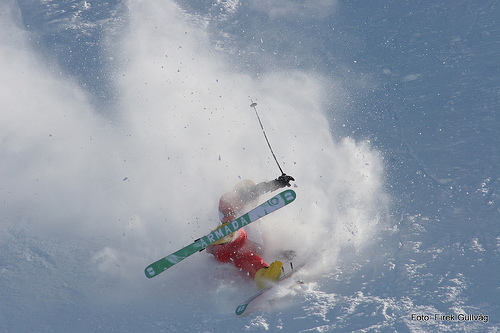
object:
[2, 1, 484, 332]
snow splash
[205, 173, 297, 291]
man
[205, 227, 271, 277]
pants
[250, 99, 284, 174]
pole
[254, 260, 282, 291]
shoe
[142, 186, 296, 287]
ski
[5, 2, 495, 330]
field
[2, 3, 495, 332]
snow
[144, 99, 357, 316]
ski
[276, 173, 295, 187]
hand